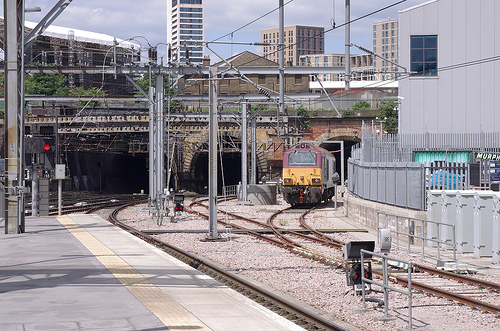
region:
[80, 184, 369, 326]
a set of railroad tracks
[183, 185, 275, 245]
a set of railroad tracks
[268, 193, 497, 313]
a set of railroad tracks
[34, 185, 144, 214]
a set of railroad tracks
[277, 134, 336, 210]
a red and yellow train engine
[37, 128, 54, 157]
a red train signal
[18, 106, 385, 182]
a train overpass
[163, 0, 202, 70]
large white building in distance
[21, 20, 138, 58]
a large white building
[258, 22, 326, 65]
a large brown building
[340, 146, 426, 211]
a grey metal fence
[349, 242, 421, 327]
a grey metal fence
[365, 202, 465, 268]
a grey metal fence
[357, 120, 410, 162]
a grey metal fence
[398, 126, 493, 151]
a grey metal fence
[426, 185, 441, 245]
a tall grey cannister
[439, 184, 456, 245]
a tall grey cannister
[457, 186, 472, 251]
a tall grey cannister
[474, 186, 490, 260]
a tall grey cannister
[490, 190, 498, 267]
a tall grey cannister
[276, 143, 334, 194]
train car is red and yellow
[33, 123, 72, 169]
light is red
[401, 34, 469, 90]
window on the building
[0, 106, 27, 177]
rust on the metal pole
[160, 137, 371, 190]
train tunnels are arched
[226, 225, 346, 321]
gravel between the train tracks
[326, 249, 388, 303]
lights in the gravel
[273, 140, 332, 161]
window wipers on the train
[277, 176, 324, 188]
headlights on the train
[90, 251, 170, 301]
brick walkway next to the tracks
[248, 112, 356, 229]
The front of a train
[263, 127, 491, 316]
A train coming in on tracks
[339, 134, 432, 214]
Metal fencing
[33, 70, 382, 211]
A bridge over train tracks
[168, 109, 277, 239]
A tunnel for trains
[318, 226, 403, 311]
A signal light at a train station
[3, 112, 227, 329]
The platform of a train station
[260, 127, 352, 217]
The engine of a train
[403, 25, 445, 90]
A six paneled window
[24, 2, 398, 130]
Buildings behind a trainyard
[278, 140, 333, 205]
A small train on the right tracks.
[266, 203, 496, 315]
Set of brown tracks a small train is on.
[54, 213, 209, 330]
A thick yellow line on the walkway.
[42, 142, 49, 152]
A red illuminated light.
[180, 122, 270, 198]
A round archway to the left of a train.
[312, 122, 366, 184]
Archway on the right a train is going through.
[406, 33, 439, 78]
A dark window on the side of a building.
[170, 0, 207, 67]
A tall white building with many windows.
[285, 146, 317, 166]
Back window of a train.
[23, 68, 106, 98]
Green trees on the left.